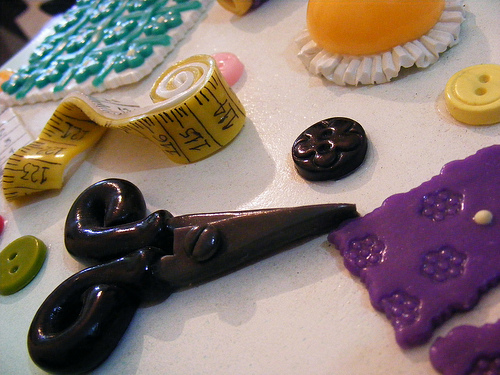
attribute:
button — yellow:
[433, 69, 496, 124]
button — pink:
[209, 50, 241, 83]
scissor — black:
[18, 167, 363, 366]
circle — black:
[287, 114, 370, 185]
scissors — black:
[26, 177, 360, 373]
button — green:
[2, 232, 50, 297]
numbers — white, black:
[173, 95, 246, 165]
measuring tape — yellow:
[2, 51, 256, 201]